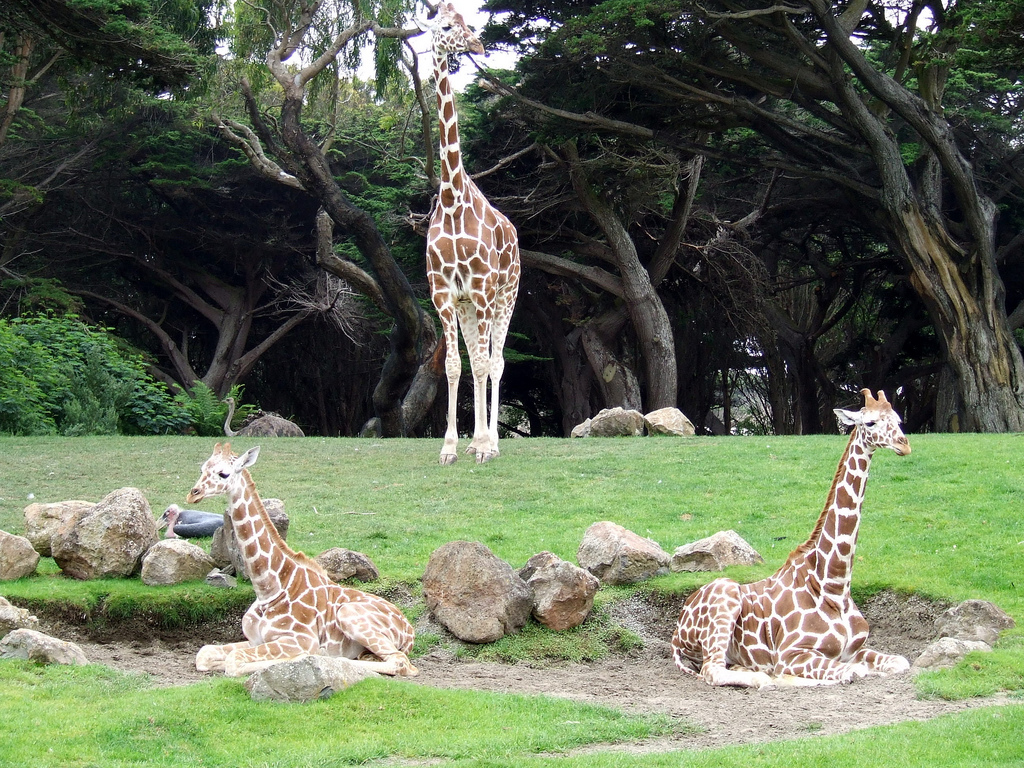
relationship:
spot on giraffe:
[464, 217, 480, 233] [395, 9, 540, 470]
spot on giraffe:
[464, 219, 484, 252] [388, 3, 561, 466]